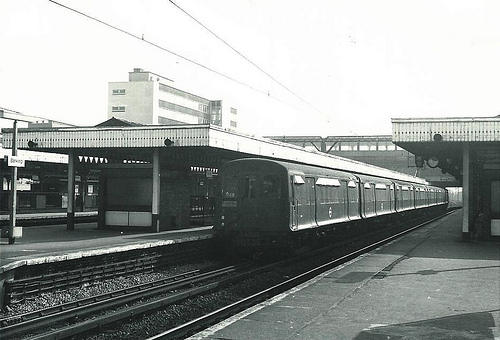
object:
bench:
[102, 210, 156, 227]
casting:
[350, 310, 500, 340]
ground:
[0, 207, 499, 340]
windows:
[374, 183, 392, 216]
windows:
[361, 182, 377, 219]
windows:
[346, 178, 362, 221]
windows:
[315, 176, 350, 227]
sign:
[8, 155, 26, 168]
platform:
[0, 227, 225, 268]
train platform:
[170, 234, 492, 340]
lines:
[44, 0, 257, 92]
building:
[107, 68, 238, 134]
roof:
[0, 122, 430, 183]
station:
[0, 109, 500, 340]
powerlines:
[47, 0, 241, 87]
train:
[203, 158, 449, 259]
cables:
[167, 0, 329, 117]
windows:
[291, 175, 317, 232]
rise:
[118, 62, 233, 139]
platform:
[183, 237, 499, 340]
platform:
[391, 116, 499, 238]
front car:
[211, 156, 362, 261]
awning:
[292, 173, 306, 186]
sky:
[153, 10, 482, 132]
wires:
[47, 0, 245, 83]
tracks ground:
[0, 244, 376, 340]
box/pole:
[9, 123, 17, 245]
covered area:
[0, 127, 432, 229]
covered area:
[391, 116, 497, 238]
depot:
[0, 126, 433, 229]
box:
[0, 173, 33, 191]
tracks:
[4, 244, 304, 340]